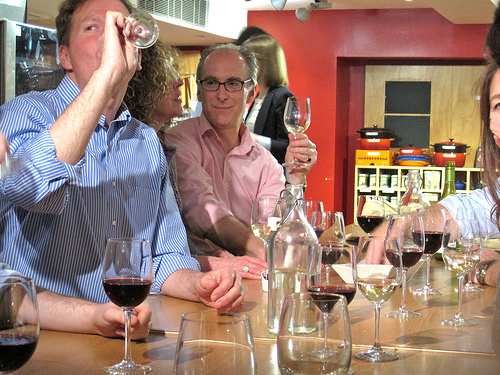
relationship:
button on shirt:
[106, 173, 125, 190] [1, 66, 218, 313]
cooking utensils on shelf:
[358, 123, 476, 172] [349, 157, 479, 215]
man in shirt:
[163, 42, 315, 263] [163, 111, 288, 261]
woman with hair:
[128, 34, 270, 279] [122, 37, 182, 127]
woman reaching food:
[364, 51, 498, 256] [346, 259, 386, 262]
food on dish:
[346, 259, 386, 262] [334, 249, 401, 289]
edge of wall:
[347, 103, 359, 132] [305, 61, 429, 163]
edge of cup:
[126, 237, 133, 249] [81, 227, 183, 321]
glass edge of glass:
[303, 291, 327, 308] [275, 291, 354, 371]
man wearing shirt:
[163, 40, 317, 264] [163, 112, 290, 242]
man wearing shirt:
[2, 2, 252, 339] [4, 69, 203, 298]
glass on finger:
[276, 95, 310, 167] [285, 132, 321, 171]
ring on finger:
[303, 155, 313, 161] [286, 151, 317, 167]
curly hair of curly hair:
[130, 45, 175, 115] [124, 45, 180, 130]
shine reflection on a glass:
[289, 98, 313, 134] [280, 95, 312, 165]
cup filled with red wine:
[100, 237, 154, 375] [102, 276, 152, 305]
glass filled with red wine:
[410, 203, 451, 298] [410, 229, 442, 259]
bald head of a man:
[206, 46, 245, 65] [173, 42, 319, 247]